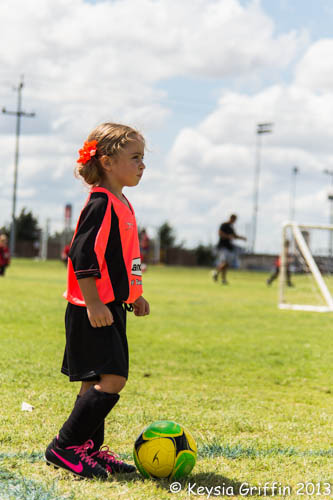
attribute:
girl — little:
[48, 127, 218, 433]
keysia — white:
[185, 478, 237, 498]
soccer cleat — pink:
[47, 435, 104, 482]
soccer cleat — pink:
[85, 440, 134, 472]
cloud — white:
[297, 40, 331, 96]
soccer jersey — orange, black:
[60, 186, 142, 308]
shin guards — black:
[58, 389, 119, 447]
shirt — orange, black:
[62, 187, 143, 306]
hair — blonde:
[74, 120, 143, 184]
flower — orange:
[67, 122, 105, 167]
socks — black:
[57, 389, 120, 448]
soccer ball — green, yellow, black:
[133, 420, 196, 480]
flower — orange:
[77, 139, 97, 166]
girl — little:
[61, 123, 149, 475]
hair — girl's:
[94, 123, 124, 149]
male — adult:
[213, 214, 248, 284]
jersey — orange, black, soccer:
[59, 181, 181, 344]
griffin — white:
[239, 480, 291, 499]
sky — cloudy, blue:
[4, 0, 332, 248]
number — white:
[292, 474, 328, 497]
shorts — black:
[42, 287, 127, 385]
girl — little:
[44, 121, 150, 482]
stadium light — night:
[248, 118, 274, 251]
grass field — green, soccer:
[175, 315, 314, 363]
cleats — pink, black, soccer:
[43, 434, 138, 482]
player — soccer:
[43, 113, 150, 498]